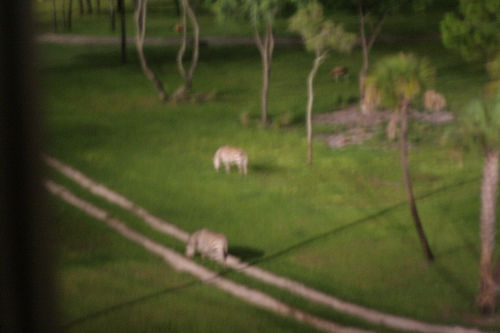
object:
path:
[36, 149, 426, 332]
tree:
[224, 4, 291, 127]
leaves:
[366, 53, 439, 117]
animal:
[209, 147, 255, 176]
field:
[0, 0, 499, 332]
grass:
[263, 166, 381, 253]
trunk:
[132, 1, 165, 98]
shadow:
[230, 241, 269, 265]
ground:
[0, 0, 499, 332]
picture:
[0, 2, 499, 332]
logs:
[258, 20, 274, 124]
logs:
[387, 107, 399, 143]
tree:
[366, 44, 450, 267]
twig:
[249, 9, 262, 38]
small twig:
[250, 1, 261, 27]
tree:
[288, 3, 357, 168]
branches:
[367, 11, 393, 56]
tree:
[62, 3, 78, 33]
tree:
[472, 149, 500, 316]